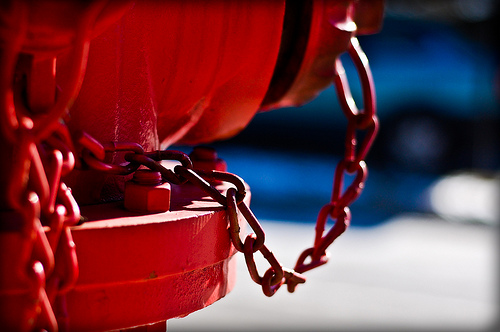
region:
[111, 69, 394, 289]
The chain on the fire hydrant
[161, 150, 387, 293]
The chain is the color red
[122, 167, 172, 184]
The screw on the fire hydrant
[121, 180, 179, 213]
The bolt on the fire hydrant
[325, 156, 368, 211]
A link on the chain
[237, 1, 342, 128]
The bottom of the water spout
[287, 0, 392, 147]
The part that comes off to connect hose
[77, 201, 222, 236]
The curve on the fire hydrant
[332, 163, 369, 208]
The link is made of metal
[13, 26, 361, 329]
The fire hydrant is used for emergencies only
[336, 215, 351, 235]
part of a chain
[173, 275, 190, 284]
part of a pole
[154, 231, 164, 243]
edge of a tank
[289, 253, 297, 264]
edge of a chain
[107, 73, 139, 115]
part of a chain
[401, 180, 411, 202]
part of a wall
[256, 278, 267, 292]
side of a chain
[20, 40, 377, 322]
The chains on the hydrant.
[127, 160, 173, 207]
The left screw on the base of the hydrant.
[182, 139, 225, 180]
The screw on the right of the base of the hydrant.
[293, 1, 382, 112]
The cap on the right side of the hydrant.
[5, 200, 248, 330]
The base of the hydrant.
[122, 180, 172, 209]
The fastener on the left screw on the base of the hydrant.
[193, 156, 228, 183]
The fastener around the right screw on the base of the hydrant.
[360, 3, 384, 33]
The tip of the cap on the right side of the hydrant.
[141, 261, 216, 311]
The chipped paint spots on the base of the fire hydrant.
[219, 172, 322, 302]
The rusted part of the chain connected to the cap on the right side of the hydrant.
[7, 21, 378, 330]
metal fire hydrant chains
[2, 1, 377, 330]
red fire hydrant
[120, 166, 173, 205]
nut and bolt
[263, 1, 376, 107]
pipe cap on fire hydrant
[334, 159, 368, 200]
link of chain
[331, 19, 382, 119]
metal attachment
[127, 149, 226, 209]
red nuts and bolts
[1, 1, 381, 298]
fire hydrant cap with retainer chain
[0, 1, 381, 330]
section of red metal fire hydrant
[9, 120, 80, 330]
red chain links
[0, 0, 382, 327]
the part of a red fire hydrant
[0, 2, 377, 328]
the chain hanging from the hydrant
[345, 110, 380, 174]
the link on the chain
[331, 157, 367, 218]
the link on the chain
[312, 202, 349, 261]
the link on the chain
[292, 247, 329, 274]
the link on the chain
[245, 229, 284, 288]
the link on the chain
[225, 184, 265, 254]
the link on the chain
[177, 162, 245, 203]
the link on the chain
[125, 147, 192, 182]
the link on the chain